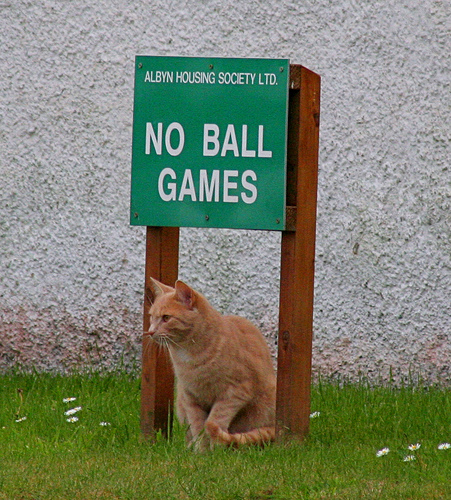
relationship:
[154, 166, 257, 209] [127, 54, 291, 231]
lettering on sign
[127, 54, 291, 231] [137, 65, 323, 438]
sign on posts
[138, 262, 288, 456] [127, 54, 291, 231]
cat under sign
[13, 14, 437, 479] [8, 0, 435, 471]
photo in daytime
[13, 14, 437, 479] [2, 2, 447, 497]
photo taken outdoors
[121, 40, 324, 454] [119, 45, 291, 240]
poles holding sign